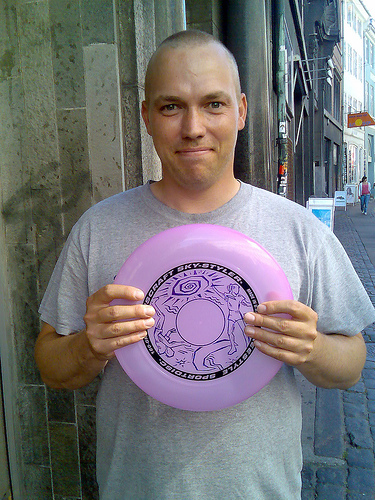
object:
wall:
[3, 2, 160, 499]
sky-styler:
[161, 257, 244, 306]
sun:
[159, 266, 212, 312]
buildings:
[341, 0, 366, 202]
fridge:
[302, 191, 336, 239]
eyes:
[201, 99, 226, 114]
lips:
[174, 146, 213, 156]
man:
[34, 28, 375, 499]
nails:
[254, 301, 269, 316]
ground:
[349, 217, 367, 237]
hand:
[241, 300, 318, 369]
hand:
[83, 282, 158, 360]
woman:
[209, 283, 252, 355]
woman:
[150, 296, 191, 358]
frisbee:
[102, 222, 299, 413]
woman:
[354, 175, 372, 215]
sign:
[348, 107, 375, 130]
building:
[303, 0, 349, 219]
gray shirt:
[32, 174, 375, 500]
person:
[357, 175, 372, 217]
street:
[300, 194, 372, 497]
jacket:
[356, 177, 372, 199]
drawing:
[140, 258, 260, 384]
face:
[146, 34, 238, 190]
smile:
[155, 77, 237, 167]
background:
[264, 41, 374, 272]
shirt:
[360, 180, 371, 197]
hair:
[358, 176, 368, 183]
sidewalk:
[298, 342, 374, 500]